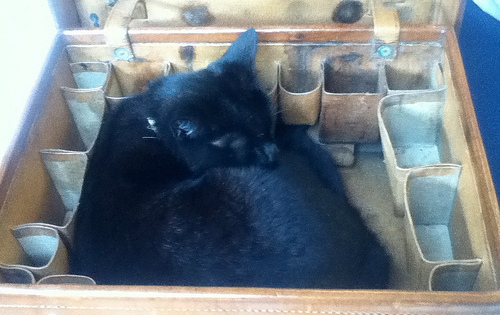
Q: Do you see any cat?
A: Yes, there is a cat.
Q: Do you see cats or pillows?
A: Yes, there is a cat.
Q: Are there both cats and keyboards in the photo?
A: No, there is a cat but no keyboards.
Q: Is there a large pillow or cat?
A: Yes, there is a large cat.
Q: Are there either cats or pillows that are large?
A: Yes, the cat is large.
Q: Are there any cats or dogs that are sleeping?
A: Yes, the cat is sleeping.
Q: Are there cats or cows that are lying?
A: Yes, the cat is lying.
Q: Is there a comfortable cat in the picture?
A: Yes, there is a comfortable cat.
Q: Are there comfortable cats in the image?
A: Yes, there is a comfortable cat.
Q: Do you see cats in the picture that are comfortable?
A: Yes, there is a cat that is comfortable.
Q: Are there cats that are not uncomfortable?
A: Yes, there is an comfortable cat.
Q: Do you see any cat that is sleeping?
A: Yes, there is a cat that is sleeping.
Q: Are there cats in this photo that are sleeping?
A: Yes, there is a cat that is sleeping.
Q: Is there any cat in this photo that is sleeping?
A: Yes, there is a cat that is sleeping.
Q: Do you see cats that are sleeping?
A: Yes, there is a cat that is sleeping.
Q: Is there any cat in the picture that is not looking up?
A: Yes, there is a cat that is sleeping.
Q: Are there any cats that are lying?
A: Yes, there is a cat that is lying.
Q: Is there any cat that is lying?
A: Yes, there is a cat that is lying.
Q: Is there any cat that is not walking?
A: Yes, there is a cat that is lying.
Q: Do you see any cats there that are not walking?
A: Yes, there is a cat that is lying .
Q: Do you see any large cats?
A: Yes, there is a large cat.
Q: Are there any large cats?
A: Yes, there is a large cat.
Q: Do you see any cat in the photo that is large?
A: Yes, there is a cat that is large.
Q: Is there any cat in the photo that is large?
A: Yes, there is a cat that is large.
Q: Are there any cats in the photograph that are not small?
A: Yes, there is a large cat.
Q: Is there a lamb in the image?
A: No, there are no lambs.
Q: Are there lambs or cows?
A: No, there are no lambs or cows.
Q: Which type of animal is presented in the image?
A: The animal is a cat.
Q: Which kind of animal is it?
A: The animal is a cat.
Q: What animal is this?
A: This is a cat.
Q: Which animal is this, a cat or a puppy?
A: This is a cat.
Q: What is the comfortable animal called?
A: The animal is a cat.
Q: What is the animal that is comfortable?
A: The animal is a cat.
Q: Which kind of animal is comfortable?
A: The animal is a cat.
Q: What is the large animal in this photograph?
A: The animal is a cat.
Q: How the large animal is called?
A: The animal is a cat.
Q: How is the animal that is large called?
A: The animal is a cat.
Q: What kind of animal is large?
A: The animal is a cat.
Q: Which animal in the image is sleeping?
A: The animal is a cat.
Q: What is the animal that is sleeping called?
A: The animal is a cat.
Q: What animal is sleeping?
A: The animal is a cat.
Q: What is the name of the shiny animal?
A: The animal is a cat.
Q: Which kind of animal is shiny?
A: The animal is a cat.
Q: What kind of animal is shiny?
A: The animal is a cat.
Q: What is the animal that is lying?
A: The animal is a cat.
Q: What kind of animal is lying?
A: The animal is a cat.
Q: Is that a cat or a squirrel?
A: That is a cat.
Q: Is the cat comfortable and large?
A: Yes, the cat is comfortable and large.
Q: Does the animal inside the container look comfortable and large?
A: Yes, the cat is comfortable and large.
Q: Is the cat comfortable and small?
A: No, the cat is comfortable but large.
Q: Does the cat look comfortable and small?
A: No, the cat is comfortable but large.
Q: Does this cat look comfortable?
A: Yes, the cat is comfortable.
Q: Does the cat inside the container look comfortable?
A: Yes, the cat is comfortable.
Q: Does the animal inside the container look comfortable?
A: Yes, the cat is comfortable.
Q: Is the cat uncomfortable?
A: No, the cat is comfortable.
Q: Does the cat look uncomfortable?
A: No, the cat is comfortable.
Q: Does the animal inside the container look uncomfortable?
A: No, the cat is comfortable.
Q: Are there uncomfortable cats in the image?
A: No, there is a cat but it is comfortable.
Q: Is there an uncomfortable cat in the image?
A: No, there is a cat but it is comfortable.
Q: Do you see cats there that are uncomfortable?
A: No, there is a cat but it is comfortable.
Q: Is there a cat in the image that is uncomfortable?
A: No, there is a cat but it is comfortable.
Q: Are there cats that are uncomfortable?
A: No, there is a cat but it is comfortable.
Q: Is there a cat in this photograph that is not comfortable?
A: No, there is a cat but it is comfortable.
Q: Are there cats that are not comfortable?
A: No, there is a cat but it is comfortable.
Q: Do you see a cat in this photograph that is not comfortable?
A: No, there is a cat but it is comfortable.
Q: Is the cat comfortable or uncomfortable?
A: The cat is comfortable.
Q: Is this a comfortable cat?
A: Yes, this is a comfortable cat.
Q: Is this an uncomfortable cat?
A: No, this is a comfortable cat.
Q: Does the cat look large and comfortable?
A: Yes, the cat is large and comfortable.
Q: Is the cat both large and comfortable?
A: Yes, the cat is large and comfortable.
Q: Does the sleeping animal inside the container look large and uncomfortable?
A: No, the cat is large but comfortable.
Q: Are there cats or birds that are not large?
A: No, there is a cat but it is large.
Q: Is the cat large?
A: Yes, the cat is large.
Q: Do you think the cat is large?
A: Yes, the cat is large.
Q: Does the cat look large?
A: Yes, the cat is large.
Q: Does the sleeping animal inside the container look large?
A: Yes, the cat is large.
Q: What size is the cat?
A: The cat is large.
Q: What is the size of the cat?
A: The cat is large.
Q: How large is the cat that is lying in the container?
A: The cat is large.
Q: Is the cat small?
A: No, the cat is large.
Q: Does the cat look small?
A: No, the cat is large.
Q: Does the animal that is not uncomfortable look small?
A: No, the cat is large.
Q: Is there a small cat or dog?
A: No, there is a cat but it is large.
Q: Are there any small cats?
A: No, there is a cat but it is large.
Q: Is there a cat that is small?
A: No, there is a cat but it is large.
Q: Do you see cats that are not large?
A: No, there is a cat but it is large.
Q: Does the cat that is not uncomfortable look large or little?
A: The cat is large.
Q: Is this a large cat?
A: Yes, this is a large cat.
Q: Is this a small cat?
A: No, this is a large cat.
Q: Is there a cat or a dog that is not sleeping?
A: No, there is a cat but it is sleeping.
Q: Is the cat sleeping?
A: Yes, the cat is sleeping.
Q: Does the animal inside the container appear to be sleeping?
A: Yes, the cat is sleeping.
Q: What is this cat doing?
A: The cat is sleeping.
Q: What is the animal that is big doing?
A: The cat is sleeping.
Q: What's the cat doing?
A: The cat is sleeping.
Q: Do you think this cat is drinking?
A: No, the cat is sleeping.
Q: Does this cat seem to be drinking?
A: No, the cat is sleeping.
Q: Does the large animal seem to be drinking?
A: No, the cat is sleeping.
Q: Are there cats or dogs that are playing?
A: No, there is a cat but it is sleeping.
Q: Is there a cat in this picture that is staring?
A: No, there is a cat but it is sleeping.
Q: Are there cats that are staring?
A: No, there is a cat but it is sleeping.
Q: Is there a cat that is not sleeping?
A: No, there is a cat but it is sleeping.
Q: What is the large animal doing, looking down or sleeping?
A: The cat is sleeping.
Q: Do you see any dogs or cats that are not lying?
A: No, there is a cat but it is lying.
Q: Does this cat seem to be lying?
A: Yes, the cat is lying.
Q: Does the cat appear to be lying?
A: Yes, the cat is lying.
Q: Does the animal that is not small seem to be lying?
A: Yes, the cat is lying.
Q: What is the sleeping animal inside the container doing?
A: The cat is lying.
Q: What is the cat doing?
A: The cat is lying.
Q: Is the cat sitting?
A: No, the cat is lying.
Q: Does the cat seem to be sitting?
A: No, the cat is lying.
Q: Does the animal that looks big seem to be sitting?
A: No, the cat is lying.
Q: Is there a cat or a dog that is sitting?
A: No, there is a cat but it is lying.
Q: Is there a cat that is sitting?
A: No, there is a cat but it is lying.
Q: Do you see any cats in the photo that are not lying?
A: No, there is a cat but it is lying.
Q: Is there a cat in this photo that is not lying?
A: No, there is a cat but it is lying.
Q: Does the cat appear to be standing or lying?
A: The cat is lying.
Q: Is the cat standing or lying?
A: The cat is lying.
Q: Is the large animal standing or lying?
A: The cat is lying.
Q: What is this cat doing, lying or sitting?
A: The cat is lying.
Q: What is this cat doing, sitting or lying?
A: The cat is lying.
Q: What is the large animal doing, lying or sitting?
A: The cat is lying.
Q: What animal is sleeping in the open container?
A: The cat is sleeping in the container.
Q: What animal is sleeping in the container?
A: The cat is sleeping in the container.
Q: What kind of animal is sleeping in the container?
A: The animal is a cat.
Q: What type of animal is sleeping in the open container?
A: The animal is a cat.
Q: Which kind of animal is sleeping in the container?
A: The animal is a cat.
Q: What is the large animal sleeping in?
A: The cat is sleeping in the container.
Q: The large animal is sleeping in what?
A: The cat is sleeping in the container.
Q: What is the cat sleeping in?
A: The cat is sleeping in the container.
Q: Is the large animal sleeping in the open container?
A: Yes, the cat is sleeping in the container.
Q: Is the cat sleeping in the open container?
A: Yes, the cat is sleeping in the container.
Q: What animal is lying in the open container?
A: The cat is lying in the container.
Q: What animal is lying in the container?
A: The cat is lying in the container.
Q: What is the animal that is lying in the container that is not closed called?
A: The animal is a cat.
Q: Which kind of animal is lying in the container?
A: The animal is a cat.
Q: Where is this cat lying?
A: The cat is lying in the container.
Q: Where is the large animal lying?
A: The cat is lying in the container.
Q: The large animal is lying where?
A: The cat is lying in the container.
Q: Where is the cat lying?
A: The cat is lying in the container.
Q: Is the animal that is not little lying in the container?
A: Yes, the cat is lying in the container.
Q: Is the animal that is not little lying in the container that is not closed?
A: Yes, the cat is lying in the container.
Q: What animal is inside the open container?
A: The cat is inside the container.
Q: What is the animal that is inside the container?
A: The animal is a cat.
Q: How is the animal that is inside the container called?
A: The animal is a cat.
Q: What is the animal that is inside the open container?
A: The animal is a cat.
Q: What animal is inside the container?
A: The animal is a cat.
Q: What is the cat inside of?
A: The cat is inside the container.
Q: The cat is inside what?
A: The cat is inside the container.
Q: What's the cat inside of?
A: The cat is inside the container.